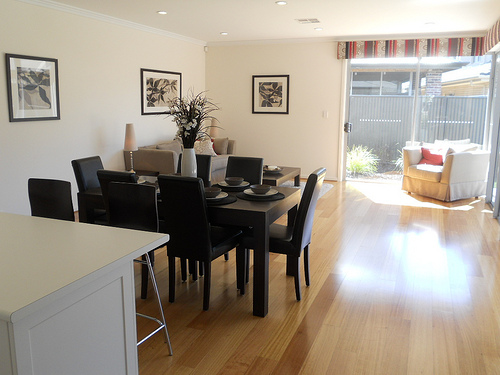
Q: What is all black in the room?
A: The table.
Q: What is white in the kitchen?
A: The counter.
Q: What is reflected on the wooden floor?
A: Sunlight.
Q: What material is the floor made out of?
A: Wood.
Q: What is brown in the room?
A: The floor.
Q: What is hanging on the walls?
A: Pictures.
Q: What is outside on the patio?
A: Tan chair.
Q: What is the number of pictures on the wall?
A: Three.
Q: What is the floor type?
A: Laminate wood.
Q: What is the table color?
A: Black.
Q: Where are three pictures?
A: On the wall.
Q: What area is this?
A: Dining area.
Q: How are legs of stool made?
A: Out of metal.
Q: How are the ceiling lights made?
A: Lights are recessed.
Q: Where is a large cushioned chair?
A: In front of sliding doors.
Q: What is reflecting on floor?
A: Sunlight.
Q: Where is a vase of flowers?
A: On dining table.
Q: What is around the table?
A: The dining chairs.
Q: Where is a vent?
A: In ceiling.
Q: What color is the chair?
A: Black.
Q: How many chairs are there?
A: 8.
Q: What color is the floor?
A: Brown.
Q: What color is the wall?
A: White.